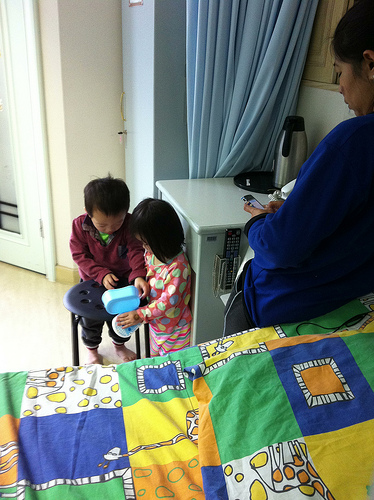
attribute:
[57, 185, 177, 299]
kids — playing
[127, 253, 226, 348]
shirt — polka dot, green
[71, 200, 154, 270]
jacket — maroon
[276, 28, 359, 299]
woman — looking, wearing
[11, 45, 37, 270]
door — white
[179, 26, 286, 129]
curtain — blue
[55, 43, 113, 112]
wall — beige, white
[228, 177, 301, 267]
phone — cell, black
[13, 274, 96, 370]
floor — yellow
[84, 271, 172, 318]
container — blue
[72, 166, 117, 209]
hair — boy, black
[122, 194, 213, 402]
girl — young, holding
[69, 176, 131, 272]
brother — playing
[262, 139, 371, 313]
jacket — blue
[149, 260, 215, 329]
polka dots — pink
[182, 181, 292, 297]
cabinet — long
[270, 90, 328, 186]
pot — silver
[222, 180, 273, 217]
remote — here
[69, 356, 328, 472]
quilt — colored, multi colored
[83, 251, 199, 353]
bowl — blue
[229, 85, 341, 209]
pitcher — black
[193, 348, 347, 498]
bedspread — green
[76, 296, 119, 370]
pants — striped